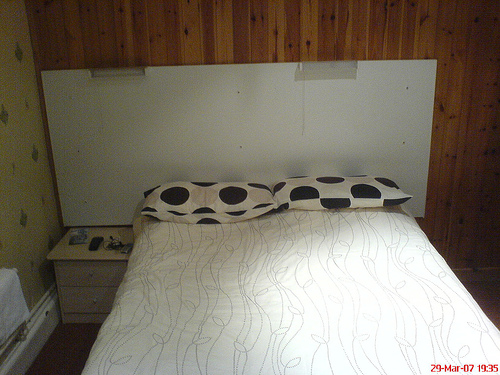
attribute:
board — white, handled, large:
[38, 62, 443, 224]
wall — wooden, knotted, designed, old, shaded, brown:
[28, 4, 500, 274]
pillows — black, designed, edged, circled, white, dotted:
[123, 173, 430, 226]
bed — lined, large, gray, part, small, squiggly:
[92, 199, 499, 375]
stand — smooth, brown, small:
[40, 226, 138, 325]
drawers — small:
[52, 261, 126, 321]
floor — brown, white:
[38, 318, 86, 374]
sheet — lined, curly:
[123, 224, 483, 368]